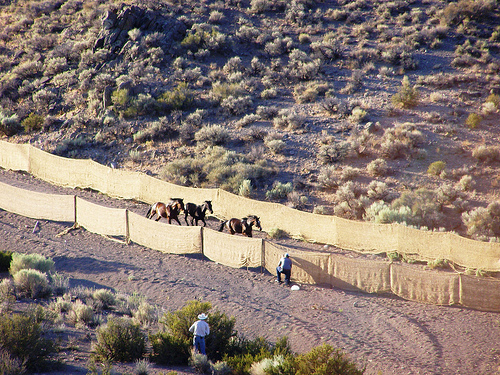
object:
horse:
[220, 213, 263, 237]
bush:
[148, 329, 191, 367]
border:
[1, 181, 499, 314]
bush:
[160, 158, 213, 186]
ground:
[2, 0, 499, 372]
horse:
[183, 199, 216, 227]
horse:
[145, 198, 187, 225]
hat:
[195, 312, 209, 318]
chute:
[0, 138, 499, 316]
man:
[274, 253, 292, 286]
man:
[186, 312, 210, 354]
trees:
[392, 72, 418, 108]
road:
[1, 167, 499, 281]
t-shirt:
[276, 254, 292, 273]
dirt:
[1, 212, 497, 375]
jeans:
[191, 336, 207, 354]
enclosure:
[0, 136, 499, 311]